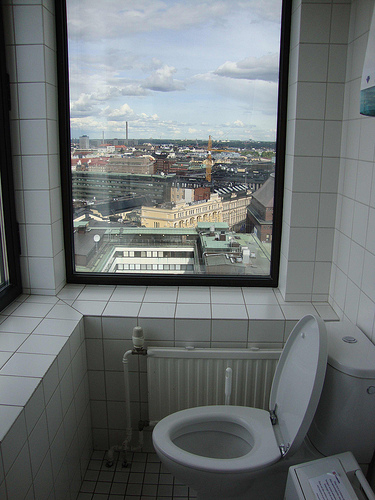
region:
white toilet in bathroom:
[156, 351, 309, 486]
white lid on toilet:
[262, 319, 329, 464]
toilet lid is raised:
[261, 290, 354, 464]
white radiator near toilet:
[122, 325, 328, 412]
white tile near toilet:
[0, 290, 238, 345]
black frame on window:
[40, 1, 325, 284]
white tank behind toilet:
[322, 338, 373, 473]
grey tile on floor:
[94, 448, 169, 498]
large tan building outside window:
[113, 175, 249, 224]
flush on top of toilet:
[329, 320, 371, 365]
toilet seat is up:
[260, 311, 328, 448]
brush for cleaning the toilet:
[207, 361, 252, 409]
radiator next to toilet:
[115, 323, 351, 415]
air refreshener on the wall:
[361, 9, 372, 132]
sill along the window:
[65, 254, 363, 326]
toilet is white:
[162, 387, 278, 498]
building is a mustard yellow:
[141, 193, 231, 223]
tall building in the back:
[116, 112, 135, 144]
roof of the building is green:
[103, 220, 240, 255]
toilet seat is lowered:
[158, 399, 252, 466]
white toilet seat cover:
[218, 323, 347, 431]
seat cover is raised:
[250, 331, 340, 484]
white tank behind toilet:
[307, 314, 362, 460]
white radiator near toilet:
[98, 339, 279, 434]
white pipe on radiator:
[103, 352, 157, 469]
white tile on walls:
[55, 284, 271, 329]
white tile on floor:
[81, 433, 144, 484]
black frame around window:
[40, 54, 305, 261]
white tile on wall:
[32, 10, 345, 288]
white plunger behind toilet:
[210, 362, 255, 403]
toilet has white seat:
[171, 403, 264, 475]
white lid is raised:
[264, 314, 326, 474]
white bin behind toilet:
[309, 320, 361, 387]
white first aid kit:
[286, 444, 341, 495]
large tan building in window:
[158, 196, 239, 228]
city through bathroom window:
[55, 13, 286, 285]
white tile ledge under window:
[54, 13, 283, 317]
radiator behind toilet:
[119, 315, 374, 492]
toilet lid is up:
[148, 315, 374, 482]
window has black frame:
[56, 95, 288, 288]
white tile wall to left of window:
[16, 98, 70, 303]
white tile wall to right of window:
[278, 94, 340, 300]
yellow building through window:
[139, 201, 219, 228]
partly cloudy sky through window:
[70, 94, 275, 141]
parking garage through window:
[71, 169, 173, 202]